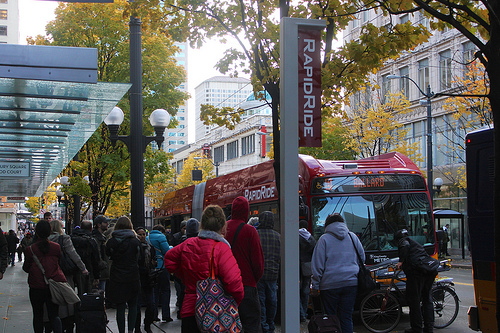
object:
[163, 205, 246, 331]
woman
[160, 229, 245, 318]
jacket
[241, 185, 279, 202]
rapid ride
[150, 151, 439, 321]
bus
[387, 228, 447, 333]
person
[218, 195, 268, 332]
person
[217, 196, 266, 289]
hoodie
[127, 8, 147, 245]
light pole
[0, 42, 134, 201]
roof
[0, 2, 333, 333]
bus stop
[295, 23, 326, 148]
flag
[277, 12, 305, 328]
pole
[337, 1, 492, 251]
buildings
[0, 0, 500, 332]
background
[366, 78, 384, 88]
leaves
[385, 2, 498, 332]
trees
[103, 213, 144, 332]
people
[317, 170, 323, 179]
lights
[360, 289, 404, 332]
wheel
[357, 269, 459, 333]
bicycle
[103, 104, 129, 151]
street light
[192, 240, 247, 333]
purse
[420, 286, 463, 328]
wheel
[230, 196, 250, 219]
hood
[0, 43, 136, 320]
stand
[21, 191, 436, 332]
crowd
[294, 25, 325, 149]
sign board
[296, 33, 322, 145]
color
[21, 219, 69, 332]
girl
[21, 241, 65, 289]
shirt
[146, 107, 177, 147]
street light